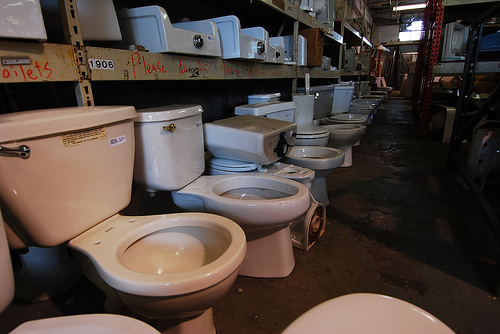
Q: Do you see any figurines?
A: No, there are no figurines.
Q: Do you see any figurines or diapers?
A: No, there are no figurines or diapers.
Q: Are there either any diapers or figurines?
A: No, there are no figurines or diapers.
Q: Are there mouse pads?
A: No, there are no mouse pads.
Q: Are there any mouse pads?
A: No, there are no mouse pads.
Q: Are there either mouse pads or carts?
A: No, there are no mouse pads or carts.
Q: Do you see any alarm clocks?
A: No, there are no alarm clocks.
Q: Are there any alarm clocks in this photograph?
A: No, there are no alarm clocks.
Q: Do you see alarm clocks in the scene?
A: No, there are no alarm clocks.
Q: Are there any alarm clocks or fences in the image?
A: No, there are no alarm clocks or fences.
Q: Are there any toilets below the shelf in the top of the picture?
A: Yes, there is a toilet below the shelf.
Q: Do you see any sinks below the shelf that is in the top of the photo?
A: No, there is a toilet below the shelf.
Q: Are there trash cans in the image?
A: No, there are no trash cans.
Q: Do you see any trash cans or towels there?
A: No, there are no trash cans or towels.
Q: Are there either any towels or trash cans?
A: No, there are no trash cans or towels.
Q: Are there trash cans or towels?
A: No, there are no trash cans or towels.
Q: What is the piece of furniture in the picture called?
A: The piece of furniture is a shelf.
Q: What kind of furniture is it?
A: The piece of furniture is a shelf.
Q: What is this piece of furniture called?
A: This is a shelf.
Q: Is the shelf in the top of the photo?
A: Yes, the shelf is in the top of the image.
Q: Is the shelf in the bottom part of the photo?
A: No, the shelf is in the top of the image.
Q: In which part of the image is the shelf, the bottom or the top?
A: The shelf is in the top of the image.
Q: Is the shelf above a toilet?
A: Yes, the shelf is above a toilet.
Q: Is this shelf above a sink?
A: No, the shelf is above a toilet.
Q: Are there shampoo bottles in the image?
A: No, there are no shampoo bottles.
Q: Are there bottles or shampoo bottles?
A: No, there are no shampoo bottles or bottles.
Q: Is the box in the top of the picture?
A: Yes, the box is in the top of the image.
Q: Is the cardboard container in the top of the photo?
A: Yes, the box is in the top of the image.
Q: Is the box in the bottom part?
A: No, the box is in the top of the image.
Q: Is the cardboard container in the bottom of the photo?
A: No, the box is in the top of the image.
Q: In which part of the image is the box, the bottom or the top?
A: The box is in the top of the image.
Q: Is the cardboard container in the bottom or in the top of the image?
A: The box is in the top of the image.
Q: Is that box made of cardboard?
A: Yes, the box is made of cardboard.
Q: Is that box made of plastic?
A: No, the box is made of cardboard.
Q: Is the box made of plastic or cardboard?
A: The box is made of cardboard.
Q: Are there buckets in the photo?
A: No, there are no buckets.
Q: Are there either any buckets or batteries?
A: No, there are no buckets or batteries.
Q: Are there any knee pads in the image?
A: No, there are no knee pads.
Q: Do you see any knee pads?
A: No, there are no knee pads.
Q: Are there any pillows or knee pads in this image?
A: No, there are no knee pads or pillows.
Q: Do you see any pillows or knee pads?
A: No, there are no knee pads or pillows.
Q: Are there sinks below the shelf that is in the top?
A: No, there is a toilet below the shelf.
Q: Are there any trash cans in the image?
A: No, there are no trash cans.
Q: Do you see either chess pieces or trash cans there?
A: No, there are no trash cans or chess pieces.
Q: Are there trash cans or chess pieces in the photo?
A: No, there are no trash cans or chess pieces.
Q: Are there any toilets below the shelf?
A: Yes, there is a toilet below the shelf.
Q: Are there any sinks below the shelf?
A: No, there is a toilet below the shelf.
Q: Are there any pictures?
A: No, there are no pictures.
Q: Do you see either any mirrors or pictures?
A: No, there are no pictures or mirrors.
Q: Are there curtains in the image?
A: No, there are no curtains.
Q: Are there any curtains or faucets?
A: No, there are no curtains or faucets.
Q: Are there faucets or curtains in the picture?
A: No, there are no curtains or faucets.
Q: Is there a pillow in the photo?
A: No, there are no pillows.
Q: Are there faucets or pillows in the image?
A: No, there are no pillows or faucets.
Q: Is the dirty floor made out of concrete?
A: Yes, the floor is made of concrete.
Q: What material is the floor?
A: The floor is made of cement.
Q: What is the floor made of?
A: The floor is made of concrete.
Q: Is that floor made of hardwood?
A: No, the floor is made of cement.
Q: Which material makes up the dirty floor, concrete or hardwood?
A: The floor is made of concrete.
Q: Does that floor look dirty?
A: Yes, the floor is dirty.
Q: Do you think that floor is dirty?
A: Yes, the floor is dirty.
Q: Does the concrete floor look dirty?
A: Yes, the floor is dirty.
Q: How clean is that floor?
A: The floor is dirty.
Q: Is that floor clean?
A: No, the floor is dirty.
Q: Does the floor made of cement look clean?
A: No, the floor is dirty.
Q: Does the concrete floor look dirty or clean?
A: The floor is dirty.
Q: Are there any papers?
A: No, there are no papers.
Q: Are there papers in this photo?
A: No, there are no papers.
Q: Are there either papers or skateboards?
A: No, there are no papers or skateboards.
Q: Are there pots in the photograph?
A: No, there are no pots.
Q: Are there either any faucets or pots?
A: No, there are no pots or faucets.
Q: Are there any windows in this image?
A: Yes, there is a window.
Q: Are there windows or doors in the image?
A: Yes, there is a window.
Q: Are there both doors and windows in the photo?
A: No, there is a window but no doors.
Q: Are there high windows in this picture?
A: Yes, there is a high window.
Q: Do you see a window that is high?
A: Yes, there is a window that is high.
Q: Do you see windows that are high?
A: Yes, there is a window that is high.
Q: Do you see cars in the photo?
A: No, there are no cars.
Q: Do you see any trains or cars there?
A: No, there are no cars or trains.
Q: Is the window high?
A: Yes, the window is high.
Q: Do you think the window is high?
A: Yes, the window is high.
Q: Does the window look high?
A: Yes, the window is high.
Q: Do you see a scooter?
A: No, there are no scooters.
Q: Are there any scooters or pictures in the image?
A: No, there are no scooters or pictures.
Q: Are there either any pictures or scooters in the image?
A: No, there are no scooters or pictures.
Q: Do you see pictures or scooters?
A: No, there are no scooters or pictures.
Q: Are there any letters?
A: Yes, there are letters.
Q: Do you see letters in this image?
A: Yes, there are letters.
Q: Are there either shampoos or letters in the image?
A: Yes, there are letters.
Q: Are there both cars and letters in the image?
A: No, there are letters but no cars.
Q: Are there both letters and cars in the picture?
A: No, there are letters but no cars.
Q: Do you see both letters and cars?
A: No, there are letters but no cars.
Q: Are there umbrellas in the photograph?
A: No, there are no umbrellas.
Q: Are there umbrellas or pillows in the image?
A: No, there are no umbrellas or pillows.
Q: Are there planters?
A: No, there are no planters.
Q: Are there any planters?
A: No, there are no planters.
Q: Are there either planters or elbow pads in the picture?
A: No, there are no planters or elbow pads.